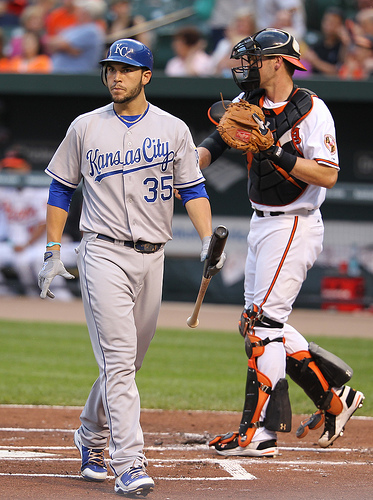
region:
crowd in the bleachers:
[8, 12, 93, 108]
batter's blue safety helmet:
[92, 30, 172, 73]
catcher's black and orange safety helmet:
[254, 24, 308, 80]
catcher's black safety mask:
[222, 31, 266, 102]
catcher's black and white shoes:
[195, 396, 370, 467]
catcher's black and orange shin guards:
[217, 329, 289, 489]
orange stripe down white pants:
[252, 211, 298, 337]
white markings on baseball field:
[163, 451, 274, 498]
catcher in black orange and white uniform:
[209, 19, 358, 481]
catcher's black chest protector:
[242, 158, 291, 207]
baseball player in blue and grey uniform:
[34, 26, 206, 499]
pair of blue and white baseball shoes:
[63, 419, 166, 498]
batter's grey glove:
[34, 247, 77, 304]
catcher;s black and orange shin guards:
[211, 333, 286, 481]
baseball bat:
[174, 213, 245, 355]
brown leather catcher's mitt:
[212, 96, 287, 167]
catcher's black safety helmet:
[252, 24, 304, 73]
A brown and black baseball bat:
[184, 222, 230, 329]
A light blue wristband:
[43, 239, 64, 249]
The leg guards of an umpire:
[206, 305, 291, 448]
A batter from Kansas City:
[38, 34, 215, 493]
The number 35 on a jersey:
[140, 174, 175, 203]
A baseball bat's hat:
[99, 37, 160, 67]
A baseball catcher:
[208, 29, 363, 452]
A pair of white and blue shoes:
[70, 427, 156, 496]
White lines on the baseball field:
[3, 420, 312, 491]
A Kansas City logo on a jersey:
[84, 137, 172, 181]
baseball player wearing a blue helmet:
[97, 20, 149, 158]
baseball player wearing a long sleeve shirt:
[30, 13, 201, 254]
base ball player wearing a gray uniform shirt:
[33, 25, 231, 260]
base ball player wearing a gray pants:
[35, 203, 166, 496]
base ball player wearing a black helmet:
[238, 9, 318, 192]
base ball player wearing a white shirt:
[224, 61, 346, 218]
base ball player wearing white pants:
[217, 197, 363, 460]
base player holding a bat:
[24, 25, 227, 361]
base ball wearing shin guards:
[193, 197, 364, 454]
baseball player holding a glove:
[215, 2, 332, 251]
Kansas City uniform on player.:
[84, 30, 196, 260]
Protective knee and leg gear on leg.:
[227, 301, 297, 445]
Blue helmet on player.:
[93, 28, 162, 119]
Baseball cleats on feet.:
[319, 377, 363, 450]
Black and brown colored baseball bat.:
[185, 212, 224, 348]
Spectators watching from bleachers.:
[10, 0, 93, 140]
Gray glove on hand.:
[30, 218, 75, 312]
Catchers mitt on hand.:
[211, 41, 287, 168]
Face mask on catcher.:
[203, 19, 336, 225]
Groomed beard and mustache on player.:
[87, 34, 173, 124]